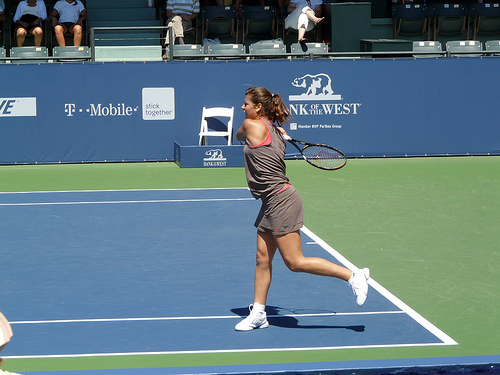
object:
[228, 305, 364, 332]
shadow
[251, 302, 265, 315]
socks white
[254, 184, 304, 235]
gray shorts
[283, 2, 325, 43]
spectator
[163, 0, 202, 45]
spectator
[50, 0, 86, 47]
spectator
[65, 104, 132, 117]
words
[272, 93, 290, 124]
ponytail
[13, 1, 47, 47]
fans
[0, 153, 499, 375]
court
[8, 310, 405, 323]
line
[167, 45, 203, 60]
bleachers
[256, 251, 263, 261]
knees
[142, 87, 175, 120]
logo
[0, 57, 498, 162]
banner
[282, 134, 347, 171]
racket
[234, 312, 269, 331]
shoes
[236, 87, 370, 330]
girl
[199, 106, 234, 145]
chair